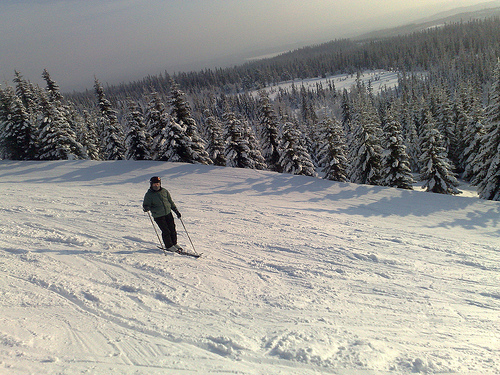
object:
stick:
[176, 217, 202, 259]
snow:
[2, 160, 495, 374]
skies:
[0, 0, 484, 101]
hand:
[177, 213, 182, 219]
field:
[0, 160, 500, 375]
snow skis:
[156, 244, 203, 257]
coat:
[142, 188, 177, 219]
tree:
[380, 111, 416, 189]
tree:
[416, 110, 464, 195]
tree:
[275, 122, 317, 178]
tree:
[158, 115, 198, 162]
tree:
[315, 114, 353, 179]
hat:
[150, 176, 161, 183]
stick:
[148, 211, 172, 258]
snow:
[38, 109, 78, 161]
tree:
[215, 103, 266, 169]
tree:
[254, 89, 281, 171]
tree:
[350, 97, 390, 187]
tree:
[37, 68, 92, 159]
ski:
[151, 239, 238, 275]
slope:
[0, 180, 500, 375]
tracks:
[0, 190, 498, 373]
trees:
[0, 67, 33, 161]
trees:
[459, 58, 499, 199]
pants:
[154, 212, 178, 248]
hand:
[143, 207, 150, 212]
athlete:
[142, 176, 183, 252]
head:
[149, 176, 160, 191]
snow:
[306, 143, 347, 166]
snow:
[411, 136, 455, 193]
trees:
[123, 94, 152, 158]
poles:
[179, 217, 197, 254]